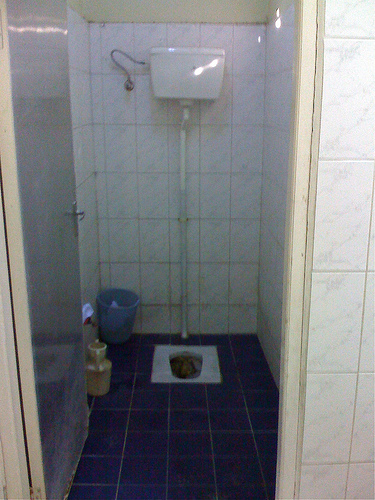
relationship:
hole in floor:
[167, 350, 205, 379] [67, 332, 280, 498]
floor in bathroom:
[67, 332, 280, 498] [7, 1, 282, 495]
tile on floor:
[228, 332, 260, 348] [67, 332, 280, 498]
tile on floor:
[133, 344, 156, 375] [67, 332, 280, 498]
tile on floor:
[126, 408, 171, 433] [67, 332, 280, 498]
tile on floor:
[74, 454, 124, 488] [67, 332, 280, 498]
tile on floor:
[214, 456, 263, 486] [67, 332, 280, 498]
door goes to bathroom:
[1, 0, 90, 499] [7, 1, 282, 495]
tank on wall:
[148, 43, 228, 103] [87, 21, 260, 333]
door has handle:
[1, 0, 90, 499] [76, 208, 88, 222]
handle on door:
[76, 208, 88, 222] [1, 0, 90, 499]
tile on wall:
[101, 22, 136, 76] [87, 21, 260, 333]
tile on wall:
[233, 25, 265, 78] [87, 21, 260, 333]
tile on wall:
[100, 71, 136, 124] [87, 21, 260, 333]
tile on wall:
[231, 75, 268, 127] [87, 21, 260, 333]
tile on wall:
[134, 123, 170, 176] [87, 21, 260, 333]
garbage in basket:
[109, 297, 120, 309] [95, 286, 140, 346]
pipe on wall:
[178, 103, 194, 341] [87, 21, 260, 333]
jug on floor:
[81, 336, 113, 396] [67, 332, 280, 498]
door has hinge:
[1, 0, 90, 499] [28, 488, 37, 500]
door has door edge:
[1, 0, 90, 499] [1, 201, 34, 500]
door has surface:
[1, 0, 90, 499] [34, 76, 53, 159]